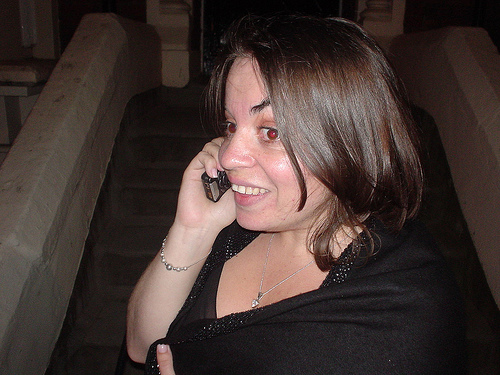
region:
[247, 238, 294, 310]
Silver necklace with heart shaped diamond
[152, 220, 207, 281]
Silver bracelet with charms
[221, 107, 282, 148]
Red eye photo reflection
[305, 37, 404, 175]
Shiny dark brown hair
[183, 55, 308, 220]
Woman talking on cell phone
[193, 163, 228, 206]
Small black cell phone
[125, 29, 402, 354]
Woman wearing a black sweater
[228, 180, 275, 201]
Woman with slightly yellow teeth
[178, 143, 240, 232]
Woman's hand holding cell phone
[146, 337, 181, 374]
Woman's thumb with shiny fingernail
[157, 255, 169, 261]
the lady is wearing a bracelet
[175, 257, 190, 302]
the lady is wearing a bracelet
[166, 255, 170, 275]
the lady is wearing a bracelet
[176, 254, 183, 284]
the lady is wearing a bracelet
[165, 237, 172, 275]
the lady is wearing a bracelet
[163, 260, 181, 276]
the lady is wearing a bracelet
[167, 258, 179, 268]
the lady is wearing a bracelet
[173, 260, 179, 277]
the lady is wearing a bracelet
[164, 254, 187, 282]
the lady is wearing a bracelet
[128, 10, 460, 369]
woman holding cell phone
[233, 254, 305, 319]
jewelry on woman's chest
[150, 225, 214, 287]
bracelet on woman's wrist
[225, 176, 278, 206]
teeth in woman's mouth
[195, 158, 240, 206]
phone on side of face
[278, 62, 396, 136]
light reflection on hair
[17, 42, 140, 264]
wall on side of stairs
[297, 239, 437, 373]
black shawl on shoulder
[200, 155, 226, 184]
finger tips on phone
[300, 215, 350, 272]
curled hair on neck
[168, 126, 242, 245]
The lady is holding a cell phone in her hand.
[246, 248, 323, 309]
The woman is wearing a silver necklace.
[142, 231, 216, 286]
The bracelet has beads on it.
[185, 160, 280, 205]
The lady is talking on the cellphone.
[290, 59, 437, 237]
The woman hair is long and brown.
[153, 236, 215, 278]
The lady is wearing a bracelet on her wrist.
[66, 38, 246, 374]
The lady is standing on a staircase.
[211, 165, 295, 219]
The lady is showing her teeth.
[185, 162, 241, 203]
The cellphone is black.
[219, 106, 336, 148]
The lady eyes are red.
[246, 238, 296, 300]
The lady is wearing a silver pendant.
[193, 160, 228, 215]
The lady is holding a cellphone.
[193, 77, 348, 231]
The lady is talking on the cellphone.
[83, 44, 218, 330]
the lady is standing in the staircase.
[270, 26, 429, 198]
The lady has long brown hair.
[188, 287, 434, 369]
The lady is wearing a black shirt.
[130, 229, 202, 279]
The bracelet has small silver beads.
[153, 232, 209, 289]
The lady is wearing a bracelet around wrist.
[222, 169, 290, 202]
The lady is showing her teeth.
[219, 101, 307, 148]
The lady has red eyes.